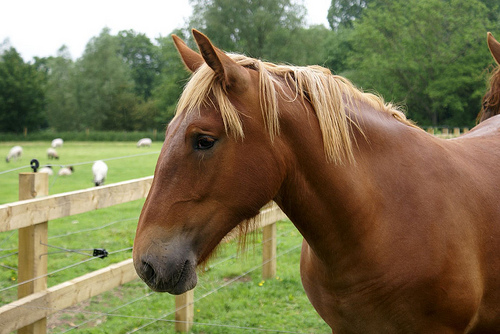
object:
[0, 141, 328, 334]
grass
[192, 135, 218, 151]
eye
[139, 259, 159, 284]
nostril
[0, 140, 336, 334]
ground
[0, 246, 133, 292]
wire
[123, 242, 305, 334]
wire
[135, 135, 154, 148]
sheep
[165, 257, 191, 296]
closed mouth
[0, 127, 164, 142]
green hedge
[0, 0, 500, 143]
background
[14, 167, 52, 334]
post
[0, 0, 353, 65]
sky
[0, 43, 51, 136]
trees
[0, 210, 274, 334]
wooden fence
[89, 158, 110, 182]
sheep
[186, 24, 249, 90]
ears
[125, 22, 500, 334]
horse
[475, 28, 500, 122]
horse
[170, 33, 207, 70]
ear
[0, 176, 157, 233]
wood fence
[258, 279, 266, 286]
dandelions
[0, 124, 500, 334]
field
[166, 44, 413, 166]
mane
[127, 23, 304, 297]
head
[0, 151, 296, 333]
fence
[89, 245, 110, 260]
clip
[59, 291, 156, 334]
wires